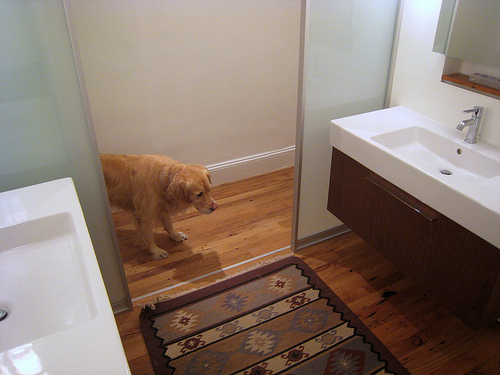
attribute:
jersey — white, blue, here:
[117, 161, 141, 210]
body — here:
[97, 154, 189, 222]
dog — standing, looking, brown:
[105, 118, 291, 259]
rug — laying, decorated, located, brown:
[158, 251, 388, 356]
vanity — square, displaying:
[396, 1, 491, 98]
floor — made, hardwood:
[351, 254, 459, 337]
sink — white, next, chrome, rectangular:
[403, 126, 482, 192]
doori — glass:
[6, 29, 72, 124]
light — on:
[427, 1, 500, 125]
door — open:
[82, 32, 367, 258]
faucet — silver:
[451, 101, 475, 146]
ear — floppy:
[165, 177, 195, 203]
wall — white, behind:
[404, 48, 436, 122]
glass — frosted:
[326, 32, 383, 70]